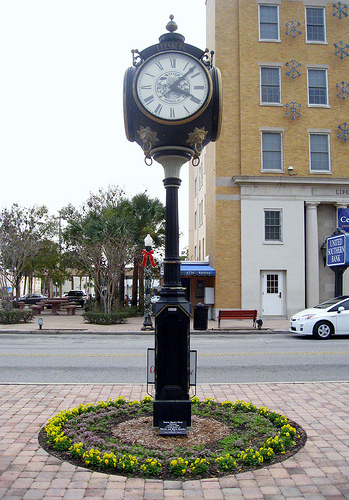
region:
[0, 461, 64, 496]
sidewalk of arranged stones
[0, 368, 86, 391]
sidewalk, curb, and street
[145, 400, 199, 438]
informational sign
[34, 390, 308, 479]
circular flower bed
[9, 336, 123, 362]
yellow line down the middle of a street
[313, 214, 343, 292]
bank's sign outside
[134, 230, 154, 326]
streetlight decorated for the holidays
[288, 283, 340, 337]
white car parked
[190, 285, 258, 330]
bench and a garbage can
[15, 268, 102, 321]
table and seats in a public space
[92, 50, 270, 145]
a clock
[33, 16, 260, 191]
a clock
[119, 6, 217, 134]
a clock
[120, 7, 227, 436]
Clock on top a metal pole.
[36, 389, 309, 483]
Ring of flowers surrounding the clock.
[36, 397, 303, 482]
Yellow and purple flowers.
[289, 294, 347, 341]
White car parked at the curb.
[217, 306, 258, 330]
Red bench.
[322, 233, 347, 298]
United Southern Bank sign.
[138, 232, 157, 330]
Street lamp covered with Christmas decorations.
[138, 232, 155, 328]
Street lamp with a red ribbon near the top.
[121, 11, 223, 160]
Clock that shows the time as 4:07.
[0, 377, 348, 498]
Brick sidewalk.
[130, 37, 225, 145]
A clock on a pole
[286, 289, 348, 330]
A parked white car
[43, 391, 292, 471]
A small circle of flowers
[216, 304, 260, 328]
A bench on the sidewalk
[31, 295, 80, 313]
A small table with chairs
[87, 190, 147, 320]
A set of trees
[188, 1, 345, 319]
A large building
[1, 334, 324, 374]
A two way road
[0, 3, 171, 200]
The cloudy sky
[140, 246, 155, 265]
A bow tied around a pole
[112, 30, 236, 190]
a clock